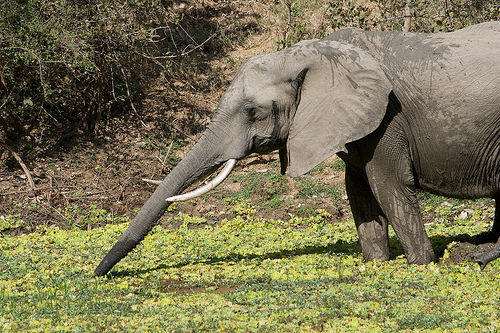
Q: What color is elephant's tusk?
A: White.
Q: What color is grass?
A: Green.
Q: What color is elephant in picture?
A: Gray.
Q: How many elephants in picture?
A: One.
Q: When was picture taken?
A: Daytime.